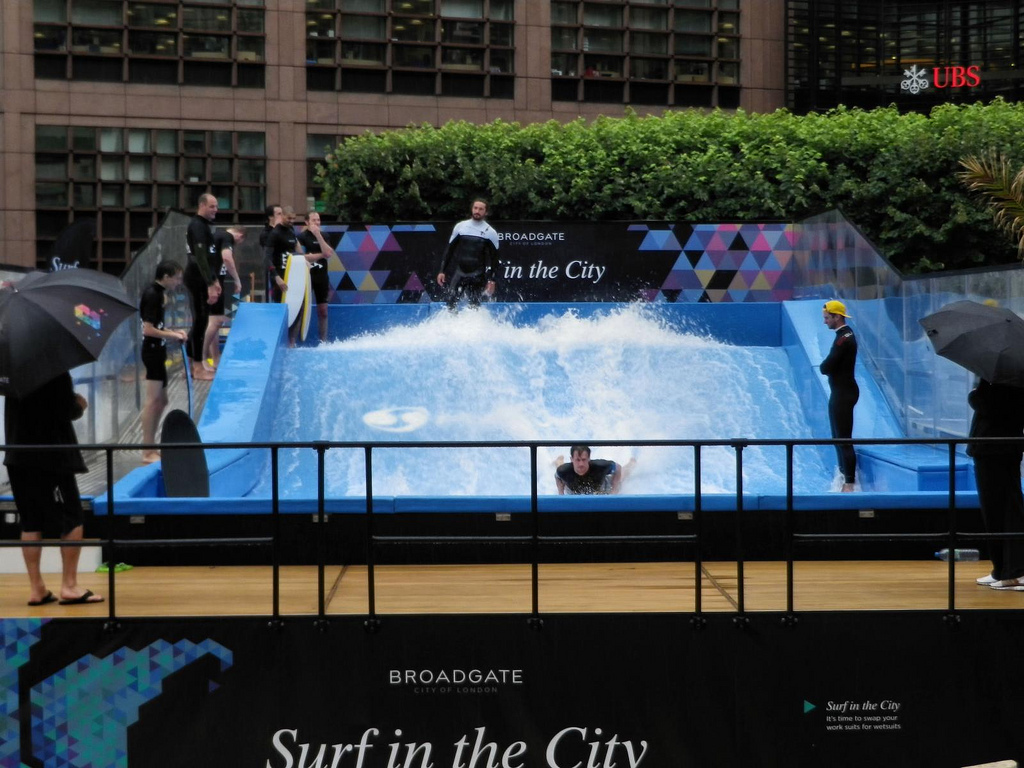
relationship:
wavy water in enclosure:
[318, 291, 765, 359] [91, 281, 980, 517]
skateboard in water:
[158, 411, 212, 491] [255, 301, 845, 492]